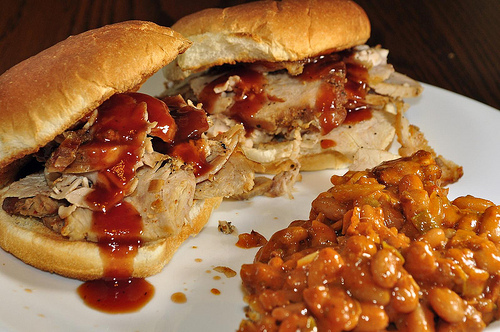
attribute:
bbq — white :
[32, 67, 219, 317]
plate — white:
[1, 70, 499, 328]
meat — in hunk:
[135, 147, 188, 228]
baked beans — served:
[238, 166, 498, 328]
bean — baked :
[243, 165, 493, 324]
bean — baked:
[294, 170, 498, 315]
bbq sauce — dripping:
[74, 205, 159, 312]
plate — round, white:
[0, 42, 498, 329]